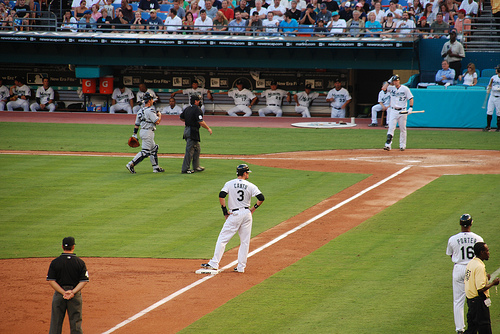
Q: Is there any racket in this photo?
A: No, there are no rackets.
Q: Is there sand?
A: Yes, there is sand.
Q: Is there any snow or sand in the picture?
A: Yes, there is sand.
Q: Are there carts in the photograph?
A: No, there are no carts.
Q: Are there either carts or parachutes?
A: No, there are no carts or parachutes.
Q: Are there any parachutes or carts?
A: No, there are no carts or parachutes.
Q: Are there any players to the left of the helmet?
A: Yes, there is a player to the left of the helmet.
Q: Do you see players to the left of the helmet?
A: Yes, there is a player to the left of the helmet.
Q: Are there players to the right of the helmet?
A: No, the player is to the left of the helmet.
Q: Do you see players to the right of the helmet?
A: No, the player is to the left of the helmet.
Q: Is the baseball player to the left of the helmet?
A: Yes, the player is to the left of the helmet.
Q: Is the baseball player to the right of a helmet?
A: No, the player is to the left of a helmet.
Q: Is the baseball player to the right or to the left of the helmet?
A: The player is to the left of the helmet.